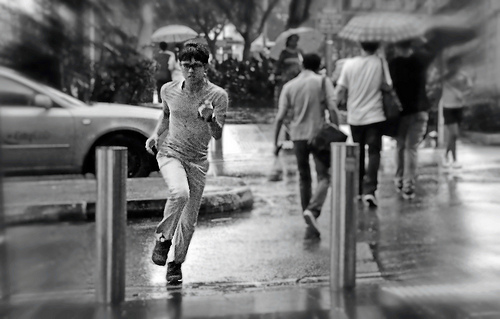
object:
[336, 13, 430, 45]
umbrella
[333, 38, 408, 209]
man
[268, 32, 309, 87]
person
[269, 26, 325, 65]
umbrella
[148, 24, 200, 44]
umbrella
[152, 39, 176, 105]
person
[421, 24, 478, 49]
umbrella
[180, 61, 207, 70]
glasses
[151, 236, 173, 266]
tennis shoes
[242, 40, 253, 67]
tree trunk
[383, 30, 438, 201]
people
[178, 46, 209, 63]
bangs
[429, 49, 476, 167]
woman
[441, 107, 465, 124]
shorts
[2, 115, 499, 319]
ground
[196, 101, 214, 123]
hand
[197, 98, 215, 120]
mobile telephone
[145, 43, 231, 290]
males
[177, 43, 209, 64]
hair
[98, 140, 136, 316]
post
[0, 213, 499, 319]
sidewalk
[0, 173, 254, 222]
curb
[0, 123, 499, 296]
road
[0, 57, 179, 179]
car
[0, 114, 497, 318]
street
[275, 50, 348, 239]
man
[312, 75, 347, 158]
bag